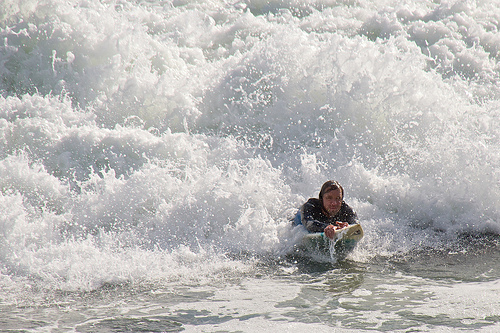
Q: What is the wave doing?
A: Crashing.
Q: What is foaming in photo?
A: Wave.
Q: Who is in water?
A: A man.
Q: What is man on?
A: Surfboard.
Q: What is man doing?
A: Surfing.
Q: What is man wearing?
A: Wetsuit.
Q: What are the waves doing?
A: Breaking.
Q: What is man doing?
A: Surfing.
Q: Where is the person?
A: On the surfboard.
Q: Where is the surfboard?
A: Under the person.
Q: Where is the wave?
A: Behind the person.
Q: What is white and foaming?
A: The wave.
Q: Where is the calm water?
A: In front of the person.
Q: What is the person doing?
A: Surfing.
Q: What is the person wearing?
A: A wetsuit.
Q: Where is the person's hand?
A: On the side of the surfboard.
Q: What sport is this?
A: Body surfing.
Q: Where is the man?
A: In the ocean.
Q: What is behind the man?
A: Waves of water.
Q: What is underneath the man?
A: A surfboard.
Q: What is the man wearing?
A: A bodysuit.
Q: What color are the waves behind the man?
A: White.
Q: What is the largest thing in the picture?
A: The waves.